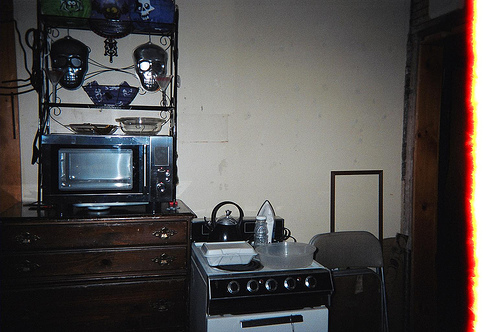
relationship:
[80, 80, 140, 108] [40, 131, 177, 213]
bowl above microwave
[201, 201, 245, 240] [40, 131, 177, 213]
tea pot above microwave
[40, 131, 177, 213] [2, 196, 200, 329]
microwave above drawer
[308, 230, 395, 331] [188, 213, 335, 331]
chair near oven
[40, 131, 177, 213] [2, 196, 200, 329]
microwave sitting on drawer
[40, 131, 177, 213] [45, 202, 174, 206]
microwave on shelf